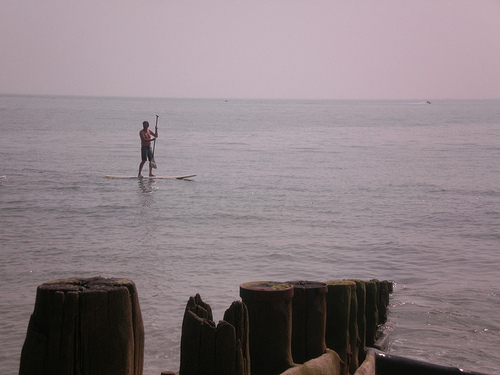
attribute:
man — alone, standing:
[134, 119, 159, 181]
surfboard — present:
[97, 169, 200, 192]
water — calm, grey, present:
[200, 95, 494, 256]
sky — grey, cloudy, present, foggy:
[15, 3, 492, 90]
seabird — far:
[422, 96, 438, 111]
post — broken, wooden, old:
[170, 287, 257, 373]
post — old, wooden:
[242, 277, 297, 371]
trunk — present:
[370, 348, 463, 369]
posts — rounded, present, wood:
[18, 265, 394, 369]